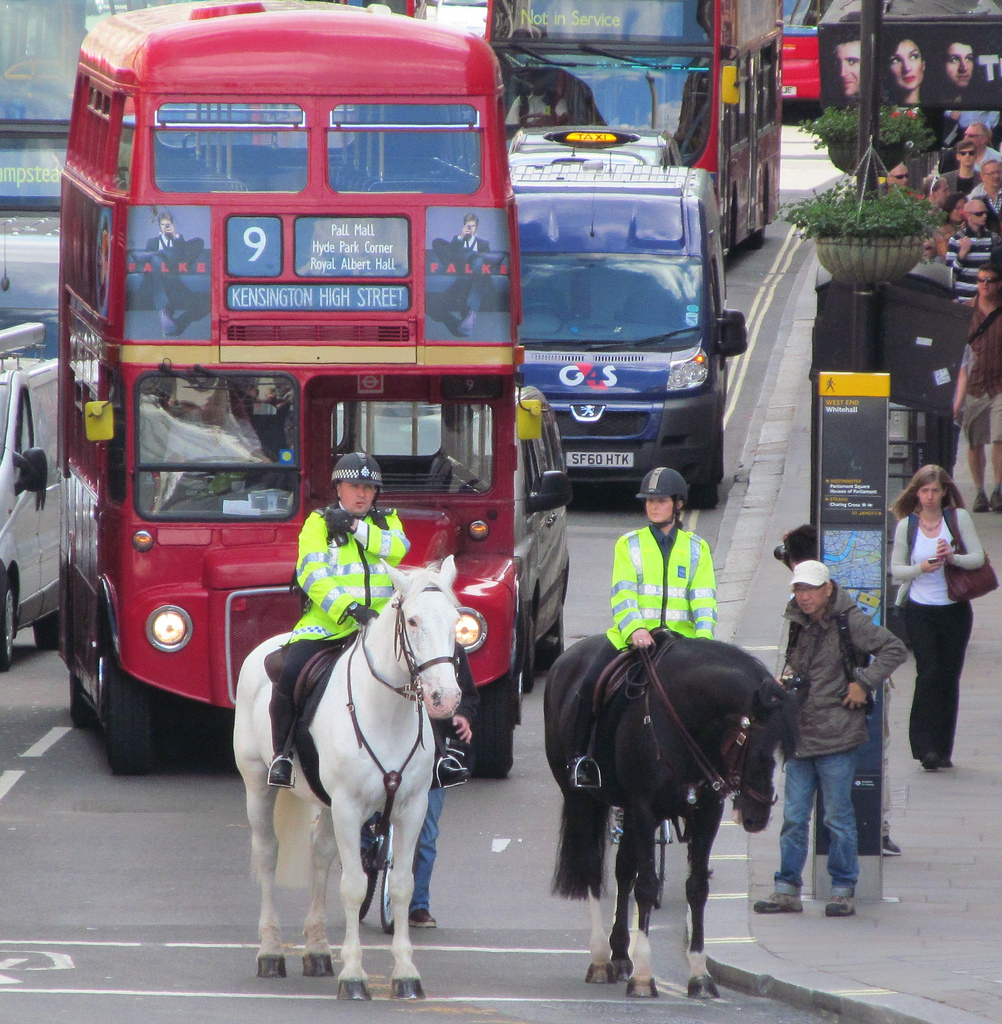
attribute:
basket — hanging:
[810, 234, 930, 292]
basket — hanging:
[826, 134, 902, 174]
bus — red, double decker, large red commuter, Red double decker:
[56, 1, 522, 775]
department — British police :
[337, 460, 378, 478]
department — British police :
[341, 460, 382, 481]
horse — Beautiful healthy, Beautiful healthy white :
[232, 548, 793, 1003]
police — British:
[257, 442, 723, 804]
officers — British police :
[264, 439, 732, 803]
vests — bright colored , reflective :
[290, 501, 723, 657]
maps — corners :
[822, 528, 885, 631]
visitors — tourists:
[758, 550, 889, 932]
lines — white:
[0, 721, 61, 835]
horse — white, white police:
[226, 559, 473, 1005]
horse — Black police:
[538, 623, 794, 1011]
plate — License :
[565, 440, 656, 476]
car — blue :
[507, 107, 747, 518]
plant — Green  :
[789, 182, 951, 249]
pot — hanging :
[782, 136, 933, 289]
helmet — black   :
[632, 457, 703, 517]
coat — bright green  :
[598, 515, 740, 646]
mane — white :
[379, 548, 440, 617]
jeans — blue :
[769, 765, 874, 907]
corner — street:
[735, 521, 897, 940]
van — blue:
[509, 166, 734, 499]